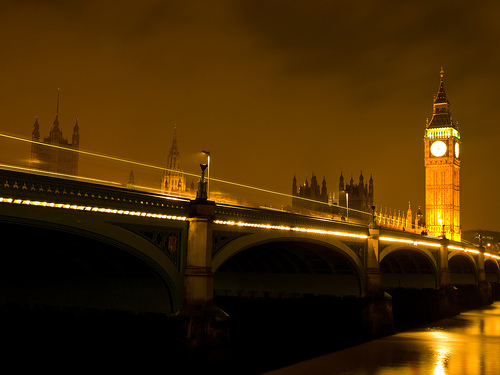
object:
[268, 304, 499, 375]
river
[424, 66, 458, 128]
top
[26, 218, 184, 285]
arches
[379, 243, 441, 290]
arches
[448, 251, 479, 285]
arches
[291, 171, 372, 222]
building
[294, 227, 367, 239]
lights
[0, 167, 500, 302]
bridge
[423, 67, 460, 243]
big ben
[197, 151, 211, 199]
street lamp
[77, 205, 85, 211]
lights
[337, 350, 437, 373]
water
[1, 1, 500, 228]
sky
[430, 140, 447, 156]
clock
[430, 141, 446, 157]
clock face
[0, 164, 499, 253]
freeway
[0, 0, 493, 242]
background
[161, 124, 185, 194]
structure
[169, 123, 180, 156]
top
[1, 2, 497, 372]
london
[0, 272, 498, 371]
shadow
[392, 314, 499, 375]
reflection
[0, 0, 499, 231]
cloud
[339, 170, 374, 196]
top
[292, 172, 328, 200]
top